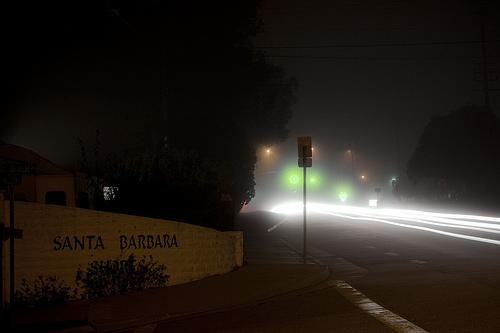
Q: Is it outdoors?
A: Yes, it is outdoors.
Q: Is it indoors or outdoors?
A: It is outdoors.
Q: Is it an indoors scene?
A: No, it is outdoors.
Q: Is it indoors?
A: No, it is outdoors.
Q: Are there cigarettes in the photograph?
A: No, there are no cigarettes.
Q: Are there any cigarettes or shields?
A: No, there are no cigarettes or shields.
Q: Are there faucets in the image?
A: No, there are no faucets.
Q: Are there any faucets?
A: No, there are no faucets.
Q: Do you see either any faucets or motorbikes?
A: No, there are no faucets or motorbikes.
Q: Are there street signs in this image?
A: Yes, there is a street sign.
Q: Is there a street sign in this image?
A: Yes, there is a street sign.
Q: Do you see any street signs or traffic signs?
A: Yes, there is a street sign.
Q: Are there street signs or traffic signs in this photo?
A: Yes, there is a street sign.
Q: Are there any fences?
A: No, there are no fences.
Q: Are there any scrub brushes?
A: No, there are no scrub brushes.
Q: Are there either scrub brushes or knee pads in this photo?
A: No, there are no scrub brushes or knee pads.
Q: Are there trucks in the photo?
A: No, there are no trucks.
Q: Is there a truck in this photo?
A: No, there are no trucks.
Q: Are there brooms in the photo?
A: No, there are no brooms.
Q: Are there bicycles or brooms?
A: No, there are no brooms or bicycles.